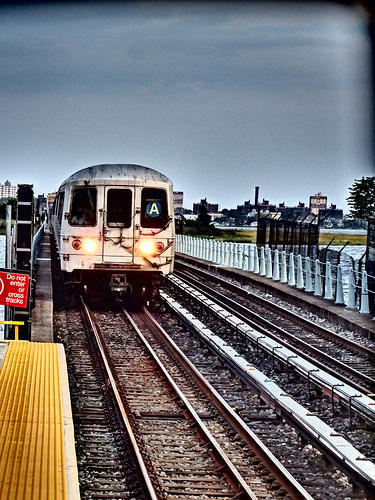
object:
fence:
[174, 232, 373, 313]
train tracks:
[51, 266, 374, 500]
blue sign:
[146, 199, 163, 218]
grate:
[0, 336, 71, 498]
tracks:
[80, 292, 326, 498]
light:
[137, 235, 165, 255]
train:
[46, 160, 179, 303]